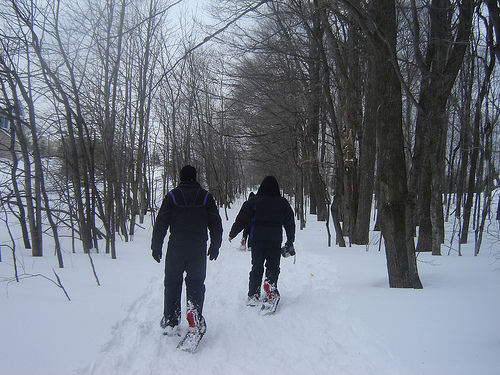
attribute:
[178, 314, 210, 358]
ski — white, red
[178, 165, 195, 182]
hat — black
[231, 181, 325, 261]
man — stepping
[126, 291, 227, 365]
skis — white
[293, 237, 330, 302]
claws — white, panda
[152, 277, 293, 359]
white skis —  white 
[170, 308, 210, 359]
claws — white, panda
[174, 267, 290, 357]
skis — white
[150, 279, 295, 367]
board — red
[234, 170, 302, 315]
man — walking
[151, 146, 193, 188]
hat — worn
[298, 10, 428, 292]
trees — bare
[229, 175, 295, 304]
person — walking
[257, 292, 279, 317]
ski — white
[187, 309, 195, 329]
board — red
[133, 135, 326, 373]
skis — white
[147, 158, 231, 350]
man — wearing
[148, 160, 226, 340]
person — wearing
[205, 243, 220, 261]
glove — black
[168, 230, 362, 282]
skis — white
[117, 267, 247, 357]
board — red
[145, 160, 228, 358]
man — walking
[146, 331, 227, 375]
board — red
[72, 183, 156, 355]
building — big and black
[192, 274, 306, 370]
panda claws — two and white